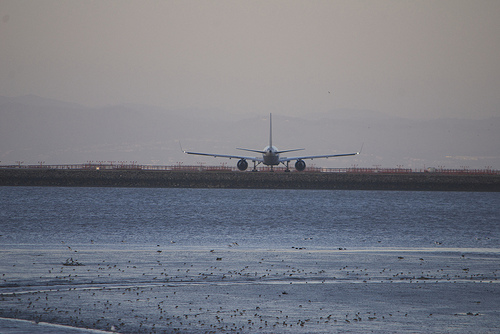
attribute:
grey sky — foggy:
[2, 3, 498, 165]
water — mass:
[356, 197, 463, 249]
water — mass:
[98, 179, 451, 224]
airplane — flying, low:
[183, 113, 358, 173]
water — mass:
[37, 196, 157, 266]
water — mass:
[48, 220, 490, 273]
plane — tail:
[178, 102, 365, 166]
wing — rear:
[289, 144, 363, 164]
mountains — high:
[13, 92, 483, 159]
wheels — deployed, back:
[251, 160, 263, 175]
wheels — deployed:
[268, 166, 275, 174]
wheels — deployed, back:
[283, 162, 294, 177]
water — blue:
[3, 186, 500, 233]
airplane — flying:
[173, 129, 378, 182]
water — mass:
[0, 185, 485, 331]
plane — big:
[178, 129, 358, 173]